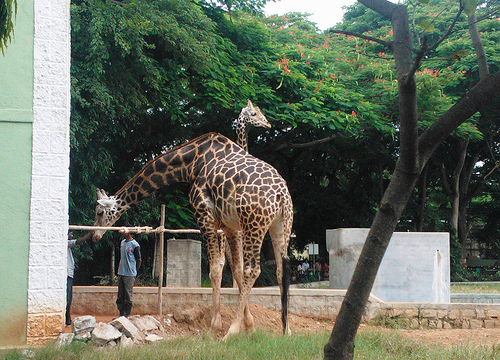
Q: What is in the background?
A: Trees.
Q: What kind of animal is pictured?
A: Giraffe's.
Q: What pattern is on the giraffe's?
A: Spots.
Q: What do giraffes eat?
A: Plants.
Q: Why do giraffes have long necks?
A: To reach plants and protect from predators.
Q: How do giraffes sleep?
A: Standing up.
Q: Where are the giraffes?
A: In a pen.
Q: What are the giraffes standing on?
A: Dirt ground.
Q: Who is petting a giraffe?
A: A male.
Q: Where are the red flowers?
A: On tree.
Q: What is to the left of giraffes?
A: Building.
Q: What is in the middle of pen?
A: Cement block.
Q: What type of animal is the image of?
A: Giraffe.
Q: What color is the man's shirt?
A: Blue.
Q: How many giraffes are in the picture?
A: Two.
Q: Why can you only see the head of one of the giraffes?
A: It's standing behind the other giraffe.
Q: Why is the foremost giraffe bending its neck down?
A: So the man can pet it's nose.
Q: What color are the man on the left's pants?
A: Blue.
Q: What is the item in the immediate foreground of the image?
A: A tree.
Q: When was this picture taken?
A: Daytime.